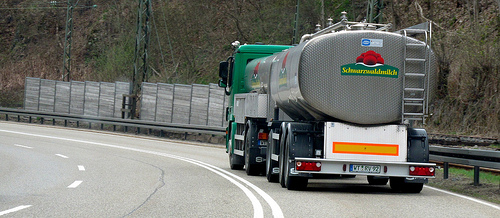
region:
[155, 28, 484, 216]
a curve in the road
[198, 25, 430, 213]
a truck on the road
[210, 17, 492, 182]
Truck driving down the road.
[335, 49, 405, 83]
Logo on the back of truck.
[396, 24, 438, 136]
Ladder on the back of truck.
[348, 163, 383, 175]
License plate on the back of truck.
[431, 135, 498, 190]
Metal guard rail beside truck.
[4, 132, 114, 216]
White lines on the road.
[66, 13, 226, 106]
Trees lining the road.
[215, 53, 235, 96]
Mirror on the side of the truck.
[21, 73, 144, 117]
Wood lining the hillside.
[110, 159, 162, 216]
Road made of asphalt.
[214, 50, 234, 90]
black window on left side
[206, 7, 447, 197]
a truck on right side of road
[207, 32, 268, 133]
cabin of truck is green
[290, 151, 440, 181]
two red lights on truck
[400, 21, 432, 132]
a ladder behind the truck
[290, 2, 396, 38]
pipes over the truck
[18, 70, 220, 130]
a wood fence on side a mountain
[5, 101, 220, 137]
rails on side the road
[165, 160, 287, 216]
two double lines in center of road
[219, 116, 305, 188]
truck has big wheels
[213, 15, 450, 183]
semi truck traveling down the road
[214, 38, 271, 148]
green cab of semi truck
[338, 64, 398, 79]
yellow lettering on green background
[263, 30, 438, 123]
tank on the semi trailer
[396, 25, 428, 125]
ladder on the tank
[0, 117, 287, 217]
yellow double line on the road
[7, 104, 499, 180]
railing along the road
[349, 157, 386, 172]
license plate on back of truck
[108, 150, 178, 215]
crack in pavement on road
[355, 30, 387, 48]
blue and white sticker on tank